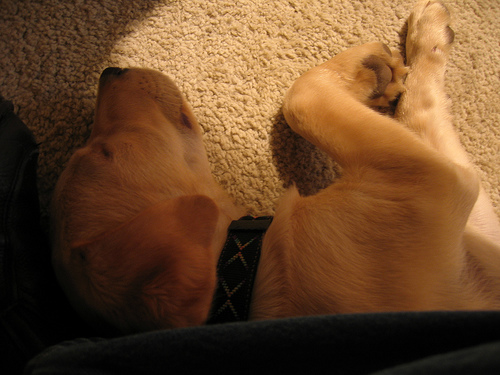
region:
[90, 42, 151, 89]
nose of the dog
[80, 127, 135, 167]
eye of the dog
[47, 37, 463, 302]
dog on the floor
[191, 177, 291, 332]
collar on the dog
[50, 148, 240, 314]
ear of the dog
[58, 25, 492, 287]
light colored dog on floor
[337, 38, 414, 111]
paw of the dog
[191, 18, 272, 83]
rug next to dog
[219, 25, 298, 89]
light hitting the rug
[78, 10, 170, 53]
shadow on the ground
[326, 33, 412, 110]
paw of a dog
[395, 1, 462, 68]
paw of a dog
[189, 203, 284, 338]
collar of a dog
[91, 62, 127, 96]
nose of a dog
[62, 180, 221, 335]
ear of a dog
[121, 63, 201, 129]
whiskers of a dog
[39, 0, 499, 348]
dog lying on the carpet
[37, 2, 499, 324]
dog is sleeping on the ground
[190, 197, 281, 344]
black collar on a dog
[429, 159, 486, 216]
elbow of a dog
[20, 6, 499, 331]
a dog lying on a carpet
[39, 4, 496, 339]
dog is color brown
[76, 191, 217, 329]
brown ear of dog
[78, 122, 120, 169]
eye of dog is close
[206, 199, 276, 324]
a black collar on neck of dog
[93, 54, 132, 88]
nose of dog is black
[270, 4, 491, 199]
front legs of dog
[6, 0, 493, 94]
a brown carpet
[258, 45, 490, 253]
leg of dog is bend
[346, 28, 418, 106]
paw of dog is black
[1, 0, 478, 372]
Dog sleeping on carpet.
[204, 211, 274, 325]
Black collar around dog's neck.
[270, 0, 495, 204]
Front paws of tan dog.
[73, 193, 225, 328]
Right ear of dog.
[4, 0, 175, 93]
Shadow on carpet.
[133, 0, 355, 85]
Light shining on carpet.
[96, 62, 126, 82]
Black nose on dog.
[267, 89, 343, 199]
Shadow of dog's paw.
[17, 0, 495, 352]
Dog sleeping on side.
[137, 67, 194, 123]
Whiskers on dog's face.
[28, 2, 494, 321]
one light colored sleeping dog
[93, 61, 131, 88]
one dark dog nose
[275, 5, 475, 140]
two dog paws against carpet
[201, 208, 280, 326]
one thick dark dog collar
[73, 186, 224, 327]
one floppy furry dog ear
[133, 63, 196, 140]
one light colored dog snout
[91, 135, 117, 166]
one right closed dog eye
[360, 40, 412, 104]
underside of one dog paw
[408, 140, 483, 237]
one right front joint of dog leg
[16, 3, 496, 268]
light colored dog on light colored carpet